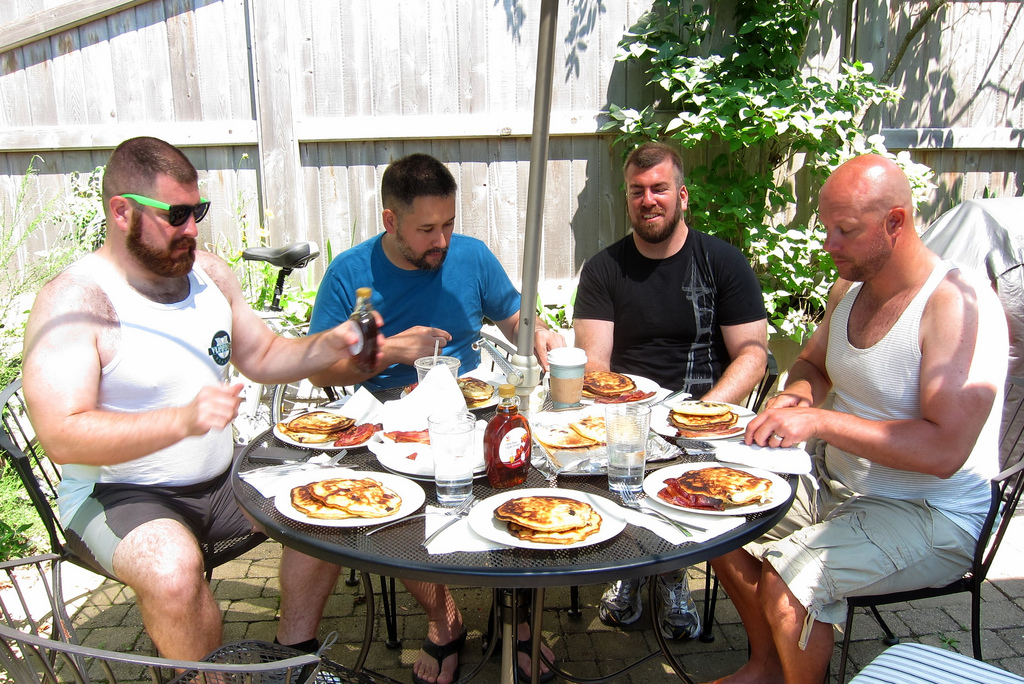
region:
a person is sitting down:
[17, 124, 390, 679]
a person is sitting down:
[303, 145, 572, 365]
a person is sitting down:
[570, 124, 780, 431]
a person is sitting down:
[708, 149, 1006, 677]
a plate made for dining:
[472, 481, 618, 558]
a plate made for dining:
[268, 461, 420, 535]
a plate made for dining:
[274, 387, 374, 464]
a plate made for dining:
[640, 380, 767, 442]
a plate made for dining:
[559, 349, 667, 406]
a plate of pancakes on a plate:
[273, 466, 428, 525]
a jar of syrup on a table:
[482, 388, 531, 486]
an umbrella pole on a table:
[502, 1, 560, 461]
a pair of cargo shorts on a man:
[720, 488, 984, 647]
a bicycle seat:
[245, 241, 318, 270]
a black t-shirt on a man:
[575, 226, 768, 388]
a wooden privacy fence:
[0, 4, 1023, 363]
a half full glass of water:
[608, 406, 651, 495]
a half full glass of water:
[429, 415, 474, 505]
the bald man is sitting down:
[706, 151, 1010, 682]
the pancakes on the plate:
[466, 483, 629, 551]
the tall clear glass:
[604, 404, 649, 493]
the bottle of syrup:
[485, 385, 530, 487]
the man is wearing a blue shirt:
[301, 154, 561, 682]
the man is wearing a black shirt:
[571, 145, 768, 639]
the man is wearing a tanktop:
[702, 149, 1004, 678]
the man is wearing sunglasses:
[20, 138, 387, 679]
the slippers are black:
[412, 609, 561, 682]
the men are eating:
[52, 71, 1017, 610]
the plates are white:
[251, 449, 638, 566]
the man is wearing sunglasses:
[81, 115, 247, 366]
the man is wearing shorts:
[17, 418, 343, 641]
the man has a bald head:
[779, 138, 928, 304]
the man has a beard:
[77, 177, 208, 304]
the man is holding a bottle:
[260, 264, 412, 408]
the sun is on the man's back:
[871, 210, 1005, 512]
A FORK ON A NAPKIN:
[416, 494, 489, 564]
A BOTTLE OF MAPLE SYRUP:
[479, 381, 540, 499]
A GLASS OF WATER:
[592, 394, 653, 503]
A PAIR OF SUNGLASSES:
[111, 185, 217, 234]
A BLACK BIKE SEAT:
[232, 236, 319, 278]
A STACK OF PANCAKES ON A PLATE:
[462, 478, 634, 558]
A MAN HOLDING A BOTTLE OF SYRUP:
[16, 128, 393, 663]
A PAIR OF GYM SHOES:
[593, 570, 710, 650]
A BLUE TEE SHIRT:
[318, 224, 540, 392]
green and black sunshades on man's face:
[111, 186, 222, 229]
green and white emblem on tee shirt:
[204, 322, 237, 370]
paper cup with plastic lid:
[548, 345, 594, 410]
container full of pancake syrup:
[481, 380, 535, 489]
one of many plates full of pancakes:
[271, 466, 430, 527]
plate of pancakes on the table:
[286, 460, 411, 537]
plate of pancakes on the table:
[646, 450, 786, 515]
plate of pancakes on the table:
[655, 386, 741, 438]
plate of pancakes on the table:
[586, 364, 660, 403]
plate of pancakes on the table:
[279, 408, 382, 451]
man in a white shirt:
[20, 130, 352, 678]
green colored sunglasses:
[119, 175, 217, 227]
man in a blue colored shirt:
[310, 147, 558, 376]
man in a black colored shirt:
[561, 131, 773, 419]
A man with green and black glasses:
[47, 136, 253, 273]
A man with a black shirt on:
[571, 234, 775, 387]